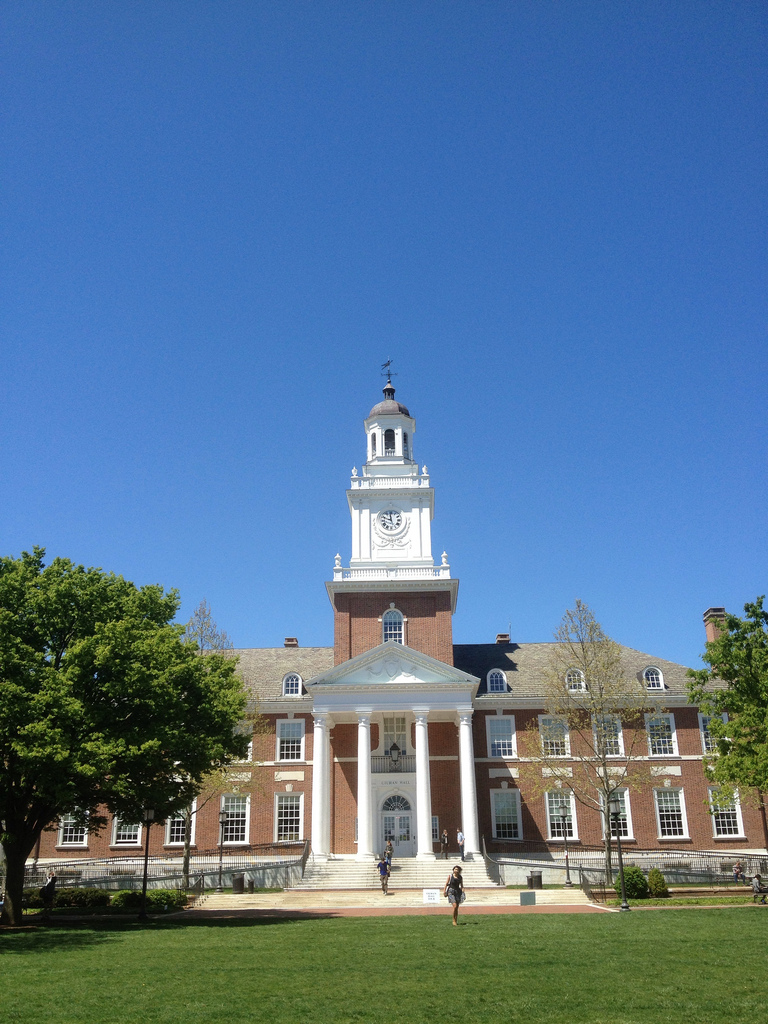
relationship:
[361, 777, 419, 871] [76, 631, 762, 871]
door of building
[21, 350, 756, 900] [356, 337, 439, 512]
building with tower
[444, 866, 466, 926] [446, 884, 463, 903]
person wearing skirt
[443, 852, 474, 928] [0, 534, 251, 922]
person under trees